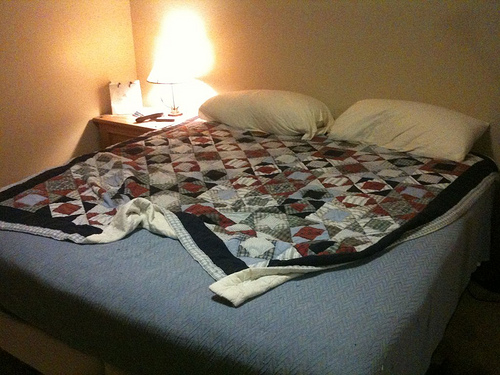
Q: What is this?
A: Bed.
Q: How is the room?
A: Neat.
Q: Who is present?
A: No one.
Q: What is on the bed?
A: Blanket.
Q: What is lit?
A: Lamp.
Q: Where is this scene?
A: In a sparsely decorated bedroom.